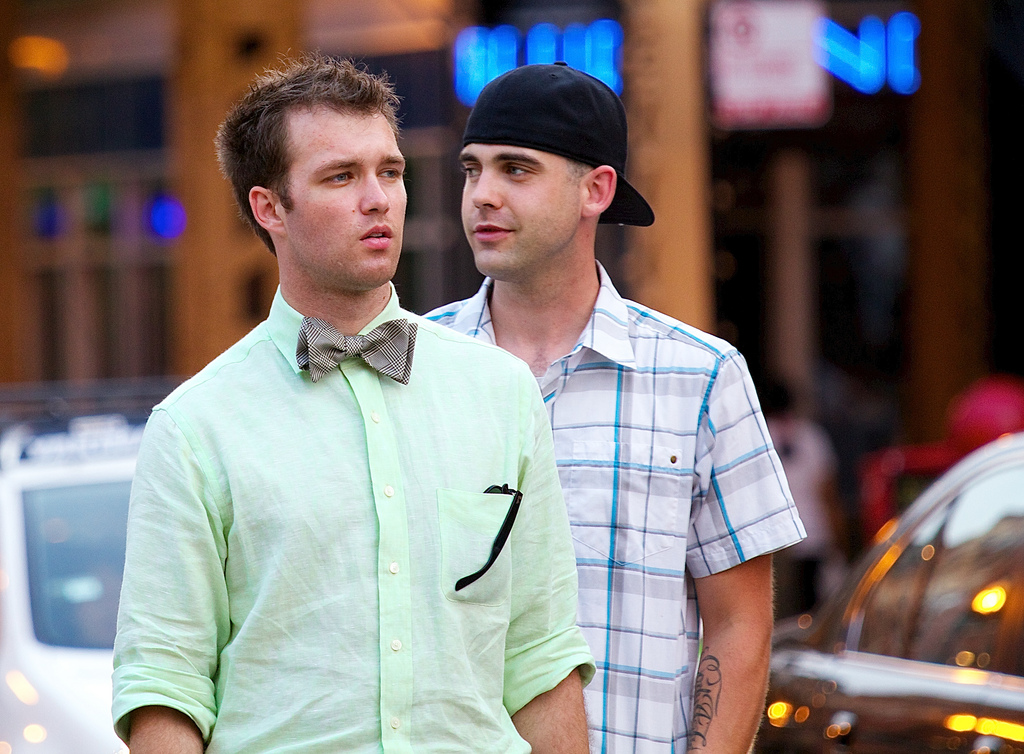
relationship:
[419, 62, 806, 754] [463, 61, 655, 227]
guy wearing a cap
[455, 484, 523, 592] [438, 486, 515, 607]
glasses in pocket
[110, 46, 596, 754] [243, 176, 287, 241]
guy has a ear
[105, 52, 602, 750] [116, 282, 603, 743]
guy wearing shirt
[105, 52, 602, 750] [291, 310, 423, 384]
guy wearing bow tie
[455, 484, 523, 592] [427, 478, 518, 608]
glasses in pocket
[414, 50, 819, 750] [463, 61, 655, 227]
guy wearing a cap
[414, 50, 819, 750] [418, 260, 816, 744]
guy wearing shirt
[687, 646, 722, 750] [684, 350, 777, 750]
tattoo on arm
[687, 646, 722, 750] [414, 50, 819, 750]
tattoo on guy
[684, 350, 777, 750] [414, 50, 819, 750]
arm on guy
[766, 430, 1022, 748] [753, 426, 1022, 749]
lights reflecting off of car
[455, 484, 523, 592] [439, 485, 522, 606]
glasses partially in pocket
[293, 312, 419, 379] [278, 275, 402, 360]
bow tie on neck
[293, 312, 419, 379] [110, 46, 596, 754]
bow tie on guy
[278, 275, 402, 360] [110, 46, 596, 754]
neck on guy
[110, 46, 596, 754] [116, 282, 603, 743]
guy wearing shirt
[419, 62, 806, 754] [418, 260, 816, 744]
guy wearing shirt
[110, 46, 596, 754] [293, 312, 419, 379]
guy wearing bow tie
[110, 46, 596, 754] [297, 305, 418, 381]
guy wearing bow tie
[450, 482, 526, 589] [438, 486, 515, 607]
glasses in pocket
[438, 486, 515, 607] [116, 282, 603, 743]
pocket on shirt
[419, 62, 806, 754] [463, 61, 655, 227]
guy wearing cap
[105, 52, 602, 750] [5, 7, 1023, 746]
guy in city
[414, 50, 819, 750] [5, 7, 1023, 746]
guy in city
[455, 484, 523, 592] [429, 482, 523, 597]
glasses in pocket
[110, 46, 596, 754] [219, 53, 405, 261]
guy has hair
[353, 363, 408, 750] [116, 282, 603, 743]
buttons on shirt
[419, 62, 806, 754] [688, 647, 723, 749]
guy has tattoo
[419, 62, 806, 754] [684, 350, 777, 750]
guy has arm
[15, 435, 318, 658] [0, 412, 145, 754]
windshield on car